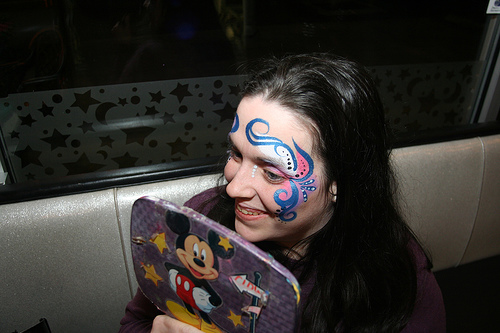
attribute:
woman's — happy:
[119, 54, 443, 332]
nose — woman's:
[225, 172, 253, 200]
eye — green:
[262, 166, 285, 185]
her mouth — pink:
[232, 201, 269, 222]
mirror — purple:
[129, 197, 300, 333]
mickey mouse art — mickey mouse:
[164, 211, 233, 331]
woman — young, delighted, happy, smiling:
[225, 51, 446, 332]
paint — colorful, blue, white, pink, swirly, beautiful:
[231, 112, 318, 223]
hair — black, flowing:
[246, 53, 417, 333]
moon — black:
[94, 99, 116, 128]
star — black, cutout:
[70, 88, 99, 114]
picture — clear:
[1, 1, 499, 332]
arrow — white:
[229, 276, 270, 304]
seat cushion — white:
[1, 186, 130, 332]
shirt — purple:
[298, 236, 442, 333]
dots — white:
[250, 162, 258, 181]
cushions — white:
[422, 134, 499, 266]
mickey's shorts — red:
[174, 274, 200, 311]